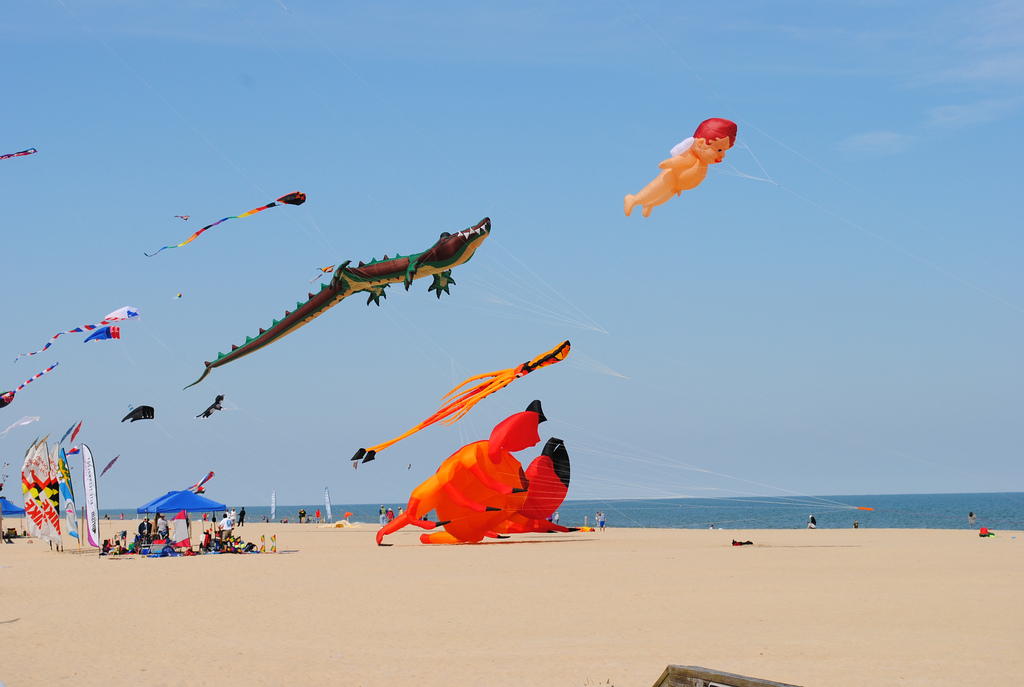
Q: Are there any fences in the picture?
A: No, there are no fences.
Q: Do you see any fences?
A: No, there are no fences.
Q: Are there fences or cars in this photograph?
A: No, there are no fences or cars.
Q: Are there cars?
A: No, there are no cars.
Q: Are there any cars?
A: No, there are no cars.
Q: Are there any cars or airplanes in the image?
A: No, there are no cars or airplanes.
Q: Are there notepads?
A: No, there are no notepads.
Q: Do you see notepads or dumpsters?
A: No, there are no notepads or dumpsters.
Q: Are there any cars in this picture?
A: No, there are no cars.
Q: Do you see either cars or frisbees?
A: No, there are no cars or frisbees.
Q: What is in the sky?
A: The clouds are in the sky.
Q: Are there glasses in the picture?
A: No, there are no glasses.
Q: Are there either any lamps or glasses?
A: No, there are no glasses or lamps.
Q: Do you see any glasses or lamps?
A: No, there are no glasses or lamps.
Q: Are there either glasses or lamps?
A: No, there are no glasses or lamps.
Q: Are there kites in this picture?
A: Yes, there is a kite.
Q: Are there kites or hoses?
A: Yes, there is a kite.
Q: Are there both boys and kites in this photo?
A: No, there is a kite but no boys.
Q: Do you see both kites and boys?
A: No, there is a kite but no boys.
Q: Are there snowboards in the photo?
A: No, there are no snowboards.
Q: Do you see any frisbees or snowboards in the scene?
A: No, there are no snowboards or frisbees.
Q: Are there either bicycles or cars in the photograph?
A: No, there are no cars or bicycles.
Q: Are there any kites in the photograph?
A: Yes, there is a kite.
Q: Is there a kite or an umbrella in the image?
A: Yes, there is a kite.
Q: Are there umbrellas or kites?
A: Yes, there is a kite.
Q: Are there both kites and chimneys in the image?
A: No, there is a kite but no chimneys.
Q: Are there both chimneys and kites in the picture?
A: No, there is a kite but no chimneys.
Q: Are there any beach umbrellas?
A: No, there are no beach umbrellas.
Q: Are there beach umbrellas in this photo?
A: No, there are no beach umbrellas.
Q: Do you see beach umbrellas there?
A: No, there are no beach umbrellas.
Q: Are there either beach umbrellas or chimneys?
A: No, there are no beach umbrellas or chimneys.